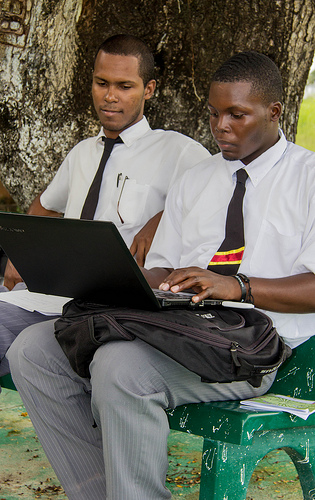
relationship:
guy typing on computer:
[3, 48, 313, 500] [0, 211, 214, 307]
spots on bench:
[208, 417, 226, 435] [1, 251, 305, 496]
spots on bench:
[178, 409, 187, 429] [1, 251, 305, 496]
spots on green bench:
[201, 444, 218, 469] [178, 387, 313, 476]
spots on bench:
[237, 459, 247, 487] [1, 251, 305, 496]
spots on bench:
[243, 427, 253, 442] [1, 251, 305, 496]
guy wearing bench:
[0, 34, 212, 405] [0, 297, 63, 376]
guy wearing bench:
[3, 48, 313, 500] [4, 316, 279, 500]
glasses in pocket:
[108, 164, 138, 236] [101, 177, 151, 231]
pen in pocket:
[113, 171, 123, 184] [101, 177, 151, 231]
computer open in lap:
[0, 211, 214, 307] [44, 294, 278, 369]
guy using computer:
[3, 48, 313, 500] [0, 211, 255, 311]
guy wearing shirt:
[3, 48, 313, 500] [142, 126, 304, 351]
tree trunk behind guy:
[0, 0, 313, 211] [3, 48, 313, 500]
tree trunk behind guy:
[0, 0, 313, 211] [0, 34, 212, 405]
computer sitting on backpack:
[0, 211, 255, 311] [54, 289, 292, 387]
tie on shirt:
[77, 130, 124, 221] [47, 114, 214, 266]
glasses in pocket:
[116, 175, 129, 224] [107, 171, 148, 230]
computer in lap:
[0, 211, 255, 311] [5, 305, 276, 375]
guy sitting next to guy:
[0, 34, 212, 405] [3, 48, 313, 500]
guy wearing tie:
[0, 34, 212, 405] [76, 136, 123, 221]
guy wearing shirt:
[0, 34, 212, 405] [0, 115, 213, 314]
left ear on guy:
[267, 99, 282, 122] [5, 51, 313, 498]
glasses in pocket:
[116, 175, 129, 224] [109, 176, 147, 226]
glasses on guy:
[116, 175, 129, 224] [0, 34, 210, 359]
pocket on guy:
[109, 176, 147, 226] [0, 34, 210, 359]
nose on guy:
[104, 87, 122, 101] [5, 26, 211, 299]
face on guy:
[93, 51, 141, 124] [5, 26, 211, 299]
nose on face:
[104, 87, 122, 101] [93, 51, 141, 124]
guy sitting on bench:
[0, 34, 212, 405] [0, 335, 313, 499]